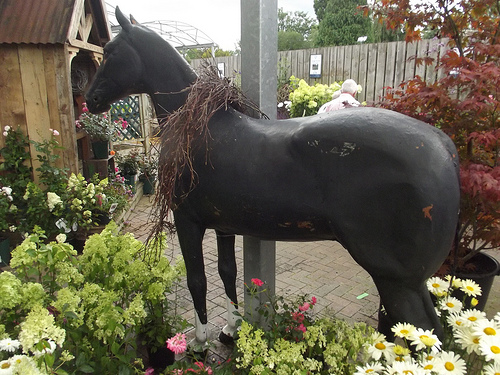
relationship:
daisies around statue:
[369, 271, 498, 373] [86, 3, 453, 355]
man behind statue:
[316, 79, 360, 114] [86, 3, 453, 355]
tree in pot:
[379, 3, 496, 273] [444, 247, 498, 307]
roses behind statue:
[1, 120, 56, 240] [86, 3, 453, 355]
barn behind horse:
[0, 0, 118, 199] [85, 6, 462, 355]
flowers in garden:
[158, 325, 220, 370] [1, 115, 499, 374]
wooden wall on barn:
[3, 46, 74, 193] [0, 0, 118, 199]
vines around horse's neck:
[172, 70, 243, 211] [159, 70, 247, 136]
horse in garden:
[85, 6, 462, 355] [22, 250, 496, 370]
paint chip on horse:
[405, 180, 446, 247] [78, 3, 489, 347]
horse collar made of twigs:
[143, 50, 260, 268] [150, 139, 184, 177]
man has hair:
[315, 79, 360, 116] [341, 79, 358, 94]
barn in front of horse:
[8, 3, 111, 199] [46, 5, 458, 265]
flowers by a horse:
[166, 332, 188, 357] [85, 3, 462, 355]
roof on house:
[0, 0, 112, 46] [3, 0, 123, 192]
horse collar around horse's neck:
[150, 61, 260, 269] [159, 70, 247, 136]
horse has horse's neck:
[85, 3, 462, 355] [159, 70, 247, 136]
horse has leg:
[85, 6, 462, 355] [170, 208, 209, 356]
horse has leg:
[85, 6, 462, 355] [211, 225, 243, 346]